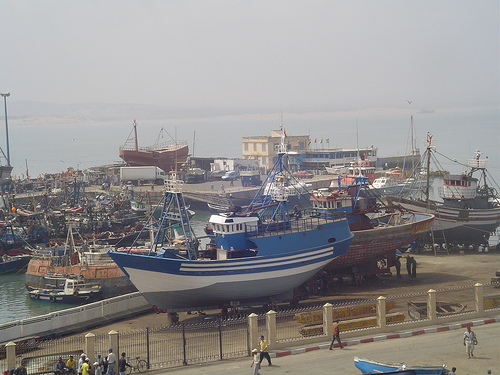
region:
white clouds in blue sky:
[32, 36, 66, 73]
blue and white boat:
[116, 239, 322, 309]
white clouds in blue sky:
[64, 25, 105, 67]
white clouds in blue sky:
[38, 71, 62, 88]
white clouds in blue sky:
[448, 51, 472, 93]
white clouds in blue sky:
[371, 37, 423, 90]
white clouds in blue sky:
[235, 46, 262, 73]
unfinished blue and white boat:
[118, 243, 330, 288]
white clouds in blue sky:
[139, 45, 184, 95]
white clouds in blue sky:
[68, 38, 113, 66]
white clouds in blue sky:
[42, 108, 75, 140]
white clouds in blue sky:
[69, 40, 103, 71]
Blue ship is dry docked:
[106, 172, 394, 347]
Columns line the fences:
[6, 301, 407, 370]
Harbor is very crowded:
[17, 127, 494, 336]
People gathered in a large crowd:
[16, 337, 127, 374]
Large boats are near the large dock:
[231, 109, 496, 326]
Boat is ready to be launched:
[397, 135, 499, 260]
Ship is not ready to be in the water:
[105, 109, 216, 180]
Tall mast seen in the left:
[1, 81, 36, 185]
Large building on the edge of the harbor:
[236, 123, 334, 195]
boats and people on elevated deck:
[10, 142, 495, 367]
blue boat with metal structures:
[102, 142, 353, 307]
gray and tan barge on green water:
[5, 245, 126, 320]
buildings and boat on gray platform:
[5, 125, 432, 212]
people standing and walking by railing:
[16, 281, 492, 366]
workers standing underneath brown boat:
[331, 200, 432, 285]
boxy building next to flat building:
[240, 130, 376, 175]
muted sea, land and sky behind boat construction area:
[7, 11, 495, 171]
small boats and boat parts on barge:
[6, 181, 191, 266]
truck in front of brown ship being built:
[114, 116, 191, 185]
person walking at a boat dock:
[463, 327, 478, 359]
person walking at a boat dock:
[328, 319, 343, 350]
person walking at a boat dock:
[256, 334, 271, 366]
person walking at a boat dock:
[249, 348, 261, 373]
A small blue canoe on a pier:
[351, 356, 451, 373]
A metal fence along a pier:
[99, 311, 492, 363]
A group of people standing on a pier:
[63, 350, 132, 374]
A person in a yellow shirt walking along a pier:
[253, 333, 274, 368]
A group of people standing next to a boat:
[370, 249, 419, 283]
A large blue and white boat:
[103, 229, 361, 306]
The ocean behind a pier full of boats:
[19, 106, 492, 179]